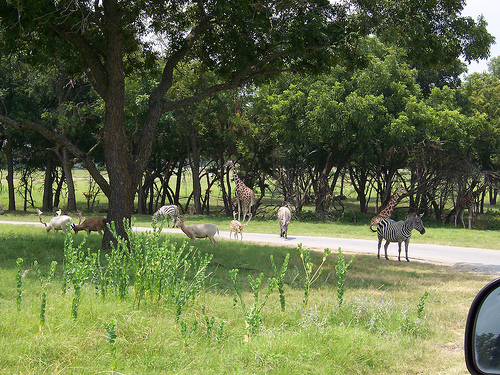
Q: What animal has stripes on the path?
A: A zebra.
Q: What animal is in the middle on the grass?
A: A giraffe.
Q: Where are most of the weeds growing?
A: In the middle of the grass.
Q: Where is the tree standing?
A: Behind the weeds.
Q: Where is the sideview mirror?
A: To the right of the grass.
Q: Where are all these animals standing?
A: On the path and in the grass.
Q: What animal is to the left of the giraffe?
A: The zebra.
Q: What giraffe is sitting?
A: The middle giraffe.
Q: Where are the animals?
A: In the road.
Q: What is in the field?
A: Tall plants.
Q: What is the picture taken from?
A: An automobile.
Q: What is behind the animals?
A: A row of trees.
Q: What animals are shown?
A: Zebra, gazelle, giraffe.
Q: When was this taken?
A: Daytime.